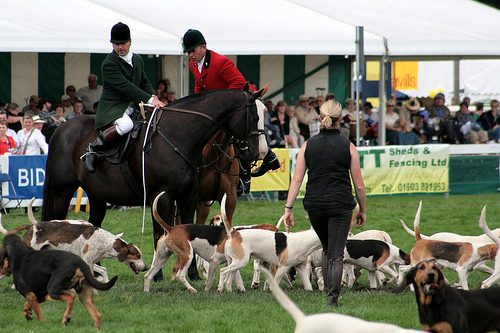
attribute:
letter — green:
[369, 149, 385, 168]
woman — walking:
[285, 99, 367, 309]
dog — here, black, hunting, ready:
[395, 261, 499, 333]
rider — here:
[83, 22, 167, 171]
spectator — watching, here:
[478, 99, 499, 143]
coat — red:
[189, 49, 258, 93]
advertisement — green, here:
[389, 148, 447, 168]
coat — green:
[95, 50, 157, 133]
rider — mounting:
[181, 28, 282, 177]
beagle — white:
[26, 196, 148, 284]